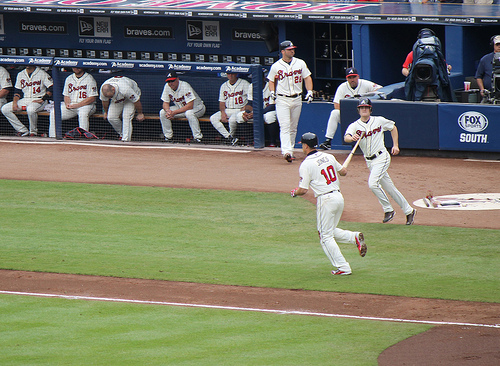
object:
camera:
[404, 30, 458, 102]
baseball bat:
[343, 132, 364, 169]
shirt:
[345, 115, 395, 157]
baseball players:
[242, 72, 276, 147]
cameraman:
[401, 28, 453, 77]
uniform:
[343, 116, 413, 215]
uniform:
[298, 149, 356, 274]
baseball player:
[344, 98, 417, 225]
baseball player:
[291, 132, 367, 275]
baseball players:
[210, 73, 250, 147]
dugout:
[2, 11, 287, 148]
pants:
[313, 183, 399, 283]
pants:
[316, 192, 359, 271]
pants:
[364, 148, 413, 216]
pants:
[275, 94, 302, 156]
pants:
[159, 103, 206, 139]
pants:
[106, 87, 141, 141]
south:
[459, 133, 487, 143]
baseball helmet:
[298, 132, 319, 148]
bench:
[1, 72, 253, 145]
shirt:
[299, 150, 344, 197]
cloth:
[404, 31, 457, 102]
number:
[321, 165, 336, 185]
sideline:
[278, 17, 498, 153]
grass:
[0, 293, 434, 366]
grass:
[2, 178, 499, 303]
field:
[0, 134, 499, 364]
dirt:
[0, 139, 499, 227]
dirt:
[2, 268, 499, 364]